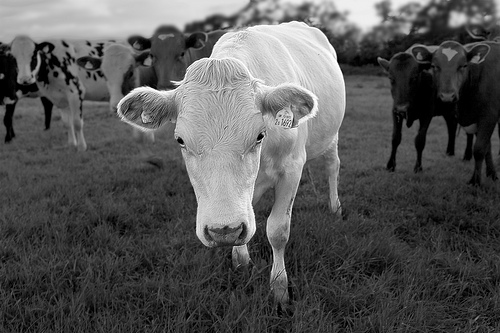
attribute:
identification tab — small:
[140, 108, 159, 124]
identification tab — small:
[272, 103, 294, 128]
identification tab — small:
[39, 44, 50, 55]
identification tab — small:
[128, 37, 146, 50]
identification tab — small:
[193, 37, 205, 50]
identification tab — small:
[415, 48, 424, 63]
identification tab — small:
[470, 54, 482, 65]